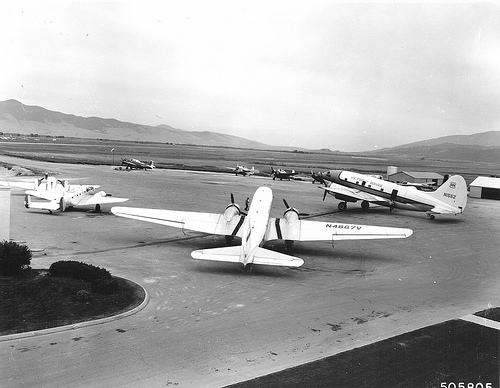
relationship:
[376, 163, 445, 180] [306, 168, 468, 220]
structure behind air plane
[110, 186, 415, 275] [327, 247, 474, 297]
air plane sitting on tarmac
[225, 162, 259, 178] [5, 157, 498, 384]
airplane sitting on tarmac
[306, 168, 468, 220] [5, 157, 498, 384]
air plane sitting on tarmac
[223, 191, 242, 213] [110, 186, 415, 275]
propeller on air plane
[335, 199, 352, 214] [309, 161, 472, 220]
wheel of air plane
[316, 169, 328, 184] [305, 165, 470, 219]
nose of airplane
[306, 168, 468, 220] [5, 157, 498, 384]
air plane on tarmac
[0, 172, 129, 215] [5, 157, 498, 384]
air plane's sitting on tarmac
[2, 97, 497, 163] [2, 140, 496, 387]
mountain range by airport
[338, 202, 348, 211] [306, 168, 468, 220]
wheel on air plane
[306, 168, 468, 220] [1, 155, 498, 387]
air plane on runway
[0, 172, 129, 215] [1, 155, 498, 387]
air plane's on runway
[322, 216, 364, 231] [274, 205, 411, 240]
black writing on plane wing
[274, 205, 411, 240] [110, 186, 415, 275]
plane wing on air plane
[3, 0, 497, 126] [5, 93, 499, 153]
bright sky over mountains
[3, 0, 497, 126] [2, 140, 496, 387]
bright sky over airport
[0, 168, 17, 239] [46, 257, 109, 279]
building behind bushes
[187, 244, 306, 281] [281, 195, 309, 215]
tail behind propeller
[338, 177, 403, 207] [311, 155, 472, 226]
stripe on plane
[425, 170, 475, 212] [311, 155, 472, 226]
tail on plane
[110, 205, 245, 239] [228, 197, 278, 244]
wing along body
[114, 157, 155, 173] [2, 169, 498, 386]
airplane on paved area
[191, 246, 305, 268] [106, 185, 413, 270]
tail on plane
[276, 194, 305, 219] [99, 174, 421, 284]
propellar of plane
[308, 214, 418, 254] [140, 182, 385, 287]
wing of air plane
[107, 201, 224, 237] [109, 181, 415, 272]
wing of air plane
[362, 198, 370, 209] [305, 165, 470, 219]
wheel of airplane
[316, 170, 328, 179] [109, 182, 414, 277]
nose of airplane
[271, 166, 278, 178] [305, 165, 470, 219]
nose of airplane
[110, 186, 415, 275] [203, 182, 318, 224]
air plane has propellers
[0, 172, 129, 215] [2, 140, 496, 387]
air plane's at airport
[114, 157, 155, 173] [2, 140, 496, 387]
airplane at airport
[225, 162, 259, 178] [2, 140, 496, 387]
airplane at airport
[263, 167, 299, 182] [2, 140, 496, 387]
airplane at airport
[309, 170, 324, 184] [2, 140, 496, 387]
airplanes at airport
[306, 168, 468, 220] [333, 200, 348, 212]
air plane has wheel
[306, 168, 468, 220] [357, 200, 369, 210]
air plane has wheel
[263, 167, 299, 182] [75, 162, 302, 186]
airplane sitting on tarmac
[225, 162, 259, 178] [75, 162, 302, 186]
airplane sitting on tarmac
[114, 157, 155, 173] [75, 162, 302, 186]
airplane sitting on tarmac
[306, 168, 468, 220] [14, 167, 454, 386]
air plane sitting on tarmac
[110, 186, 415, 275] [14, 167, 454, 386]
air plane sitting on tarmac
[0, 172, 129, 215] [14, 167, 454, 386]
air plane's sitting on tarmac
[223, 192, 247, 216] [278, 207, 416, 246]
propeller on wing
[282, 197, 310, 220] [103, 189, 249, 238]
propellar on wing